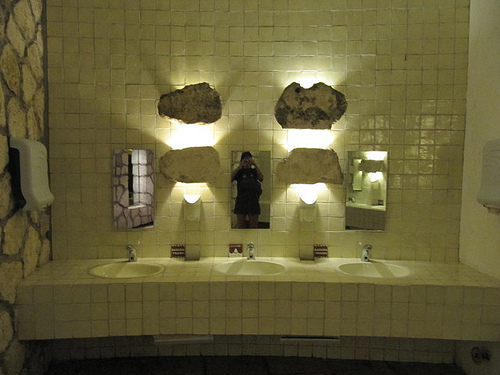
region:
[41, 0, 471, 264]
Tiled wall in the bathroom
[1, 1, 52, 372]
Rock wall to the left of the room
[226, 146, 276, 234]
Mirror with reflection of camera man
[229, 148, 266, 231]
Reflection of camera man in the mirror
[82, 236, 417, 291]
Three sinks on the countertop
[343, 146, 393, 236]
Mirror on the right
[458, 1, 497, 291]
White stucco wall to the right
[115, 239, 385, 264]
Three silver faucets above the sinks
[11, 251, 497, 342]
Tile counter with three sinks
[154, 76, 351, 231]
Light fixtures above the sink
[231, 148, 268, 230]
the man is in the mirror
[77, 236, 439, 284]
the sinks are three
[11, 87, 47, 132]
the wall has rocks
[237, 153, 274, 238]
man is taking a photo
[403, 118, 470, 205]
light reflection is on the wall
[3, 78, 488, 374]
the scene is a public restroom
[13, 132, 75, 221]
the dryer is on the wall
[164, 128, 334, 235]
the light is shining on the wall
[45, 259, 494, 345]
the sink is clean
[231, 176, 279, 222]
man is wearing shorts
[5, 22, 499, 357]
a public bathroom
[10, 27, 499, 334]
a public bathroom sink area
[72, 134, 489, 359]
three public bathroom sinks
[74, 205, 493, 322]
three sinks in a counter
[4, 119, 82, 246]
towel dispenser on wall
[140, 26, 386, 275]
rocks on the wall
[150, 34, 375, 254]
lighted rocks on the wall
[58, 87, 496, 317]
two mirrors on the wall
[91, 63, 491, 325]
three small mirrors on the wall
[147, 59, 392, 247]
lighted rocks on a bathroom wall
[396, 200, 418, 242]
part of a wall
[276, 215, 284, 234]
part of a wall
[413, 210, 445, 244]
part of a wall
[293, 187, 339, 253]
part of a light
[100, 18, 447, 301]
four lighted rocks on the wall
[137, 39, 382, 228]
a wall with lighted rocks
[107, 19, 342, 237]
a wall with four lighted rocks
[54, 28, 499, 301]
a bathroom with lighted rocks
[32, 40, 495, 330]
a public bathroom with lighted rocks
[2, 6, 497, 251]
lighted rocks in a bathroom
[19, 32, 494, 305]
lighted rocks in a public rocks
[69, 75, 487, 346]
three mirrors on the wall